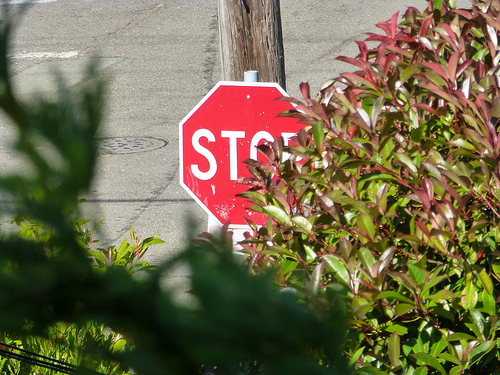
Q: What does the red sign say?
A: Stop.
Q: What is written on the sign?
A: Stop.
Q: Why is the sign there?
A: To make people stop.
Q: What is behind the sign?
A: Pole.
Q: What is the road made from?
A: Tar.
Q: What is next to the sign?
A: Bush.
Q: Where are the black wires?
A: Bottom left.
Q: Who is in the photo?
A: No body.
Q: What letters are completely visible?
A: S T.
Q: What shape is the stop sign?
A: Octagon.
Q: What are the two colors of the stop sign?
A: Red and white.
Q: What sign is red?
A: The stop sign.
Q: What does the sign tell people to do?
A: Stop.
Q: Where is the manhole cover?
A: In the street.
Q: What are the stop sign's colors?
A: Red and white.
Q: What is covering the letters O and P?
A: Bushes.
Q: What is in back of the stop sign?
A: A wooden post.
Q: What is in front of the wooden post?
A: A stop sign.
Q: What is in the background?
A: A street corner.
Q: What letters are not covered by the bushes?
A: S and T.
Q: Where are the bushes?
A: In front of the stop sign.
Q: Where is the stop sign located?
A: Near pole.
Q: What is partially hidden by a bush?
A: Stop sign.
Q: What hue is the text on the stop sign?
A: White.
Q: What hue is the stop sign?
A: Red.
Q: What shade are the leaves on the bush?
A: Red and green.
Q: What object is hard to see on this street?
A: The stop sign.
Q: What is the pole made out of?
A: Wood.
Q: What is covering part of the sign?
A: The bush.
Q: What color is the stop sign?
A: Red and white.